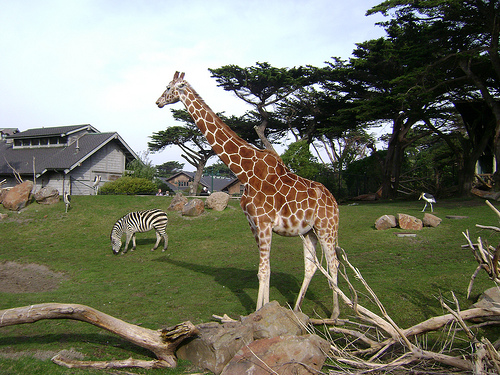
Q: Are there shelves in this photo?
A: No, there are no shelves.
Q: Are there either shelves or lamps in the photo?
A: No, there are no shelves or lamps.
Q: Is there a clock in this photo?
A: No, there are no clocks.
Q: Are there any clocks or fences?
A: No, there are no clocks or fences.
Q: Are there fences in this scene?
A: No, there are no fences.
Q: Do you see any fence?
A: No, there are no fences.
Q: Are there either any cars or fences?
A: No, there are no fences or cars.